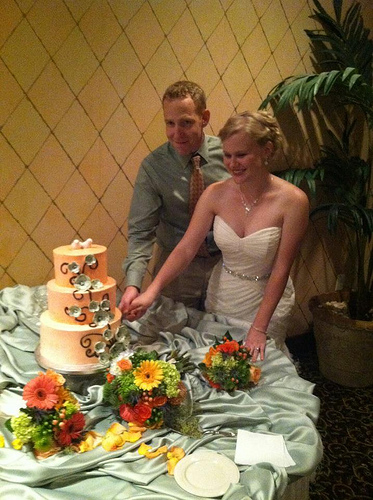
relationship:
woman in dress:
[120, 107, 315, 352] [183, 219, 281, 345]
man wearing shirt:
[117, 81, 238, 312] [117, 132, 244, 295]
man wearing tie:
[117, 81, 238, 312] [183, 152, 208, 261]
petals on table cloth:
[84, 417, 186, 495] [145, 312, 198, 351]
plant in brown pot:
[259, 0, 371, 313] [311, 291, 371, 383]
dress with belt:
[206, 212, 294, 350] [217, 257, 271, 288]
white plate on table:
[172, 447, 242, 499] [1, 282, 323, 498]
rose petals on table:
[78, 424, 178, 475] [1, 282, 323, 498]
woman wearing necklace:
[120, 107, 315, 352] [233, 180, 271, 209]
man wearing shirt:
[117, 81, 238, 312] [120, 134, 233, 287]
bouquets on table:
[5, 327, 268, 458] [5, 246, 331, 496]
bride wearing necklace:
[126, 113, 307, 362] [230, 195, 261, 212]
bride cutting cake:
[126, 113, 307, 362] [35, 231, 126, 377]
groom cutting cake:
[120, 85, 226, 310] [35, 231, 126, 377]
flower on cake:
[83, 252, 94, 262] [39, 236, 131, 374]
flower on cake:
[74, 275, 91, 289] [39, 236, 131, 374]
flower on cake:
[87, 300, 95, 310] [39, 236, 131, 374]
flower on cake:
[68, 304, 81, 317] [39, 236, 131, 374]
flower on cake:
[94, 337, 105, 353] [39, 236, 131, 374]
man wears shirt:
[117, 81, 238, 312] [120, 134, 233, 287]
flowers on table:
[90, 347, 191, 427] [1, 282, 323, 498]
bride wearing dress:
[126, 113, 307, 362] [180, 106, 311, 371]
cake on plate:
[35, 231, 126, 377] [33, 339, 122, 374]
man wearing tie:
[117, 81, 238, 312] [186, 153, 210, 257]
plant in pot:
[259, 0, 371, 313] [304, 288, 360, 389]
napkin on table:
[217, 405, 294, 460] [1, 282, 323, 498]